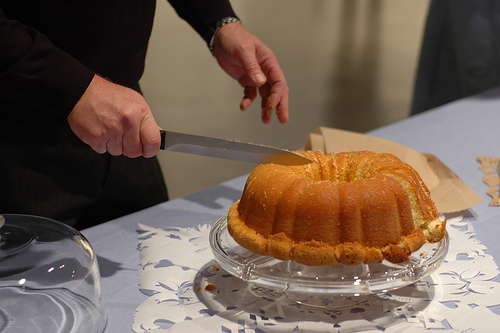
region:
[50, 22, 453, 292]
cutting a cake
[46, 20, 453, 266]
the knife is long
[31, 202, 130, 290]
the glass lid for the cake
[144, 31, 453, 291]
this is a bundt cake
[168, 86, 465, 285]
the cake is on glass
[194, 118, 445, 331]
the cake is golden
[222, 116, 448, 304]
the cake has no frosting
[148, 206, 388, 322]
cake is on white decor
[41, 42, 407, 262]
one hand holds a knife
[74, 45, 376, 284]
about to cut a cake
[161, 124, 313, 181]
silver blade of a knife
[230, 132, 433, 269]
golden colored bundt cake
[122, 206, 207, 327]
lacy white paper table doily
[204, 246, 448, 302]
clear glass cake stand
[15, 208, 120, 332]
clear cake dome topper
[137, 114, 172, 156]
black handle of a knife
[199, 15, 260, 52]
wrist watch on a hand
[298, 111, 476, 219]
brown napkin beside the bundt cake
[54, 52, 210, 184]
hand holding a knife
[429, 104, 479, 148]
grey colored table top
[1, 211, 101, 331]
top of the cake dish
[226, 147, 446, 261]
pound cake on platter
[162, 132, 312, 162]
knife cutting the cake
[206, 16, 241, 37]
bracelet on person's left hand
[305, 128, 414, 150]
brown paper towel on table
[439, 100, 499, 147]
blue table cloth over table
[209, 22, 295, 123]
the person's left hand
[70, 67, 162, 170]
the person's right hand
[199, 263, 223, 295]
cake crumbs on table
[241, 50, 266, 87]
the person's left thumb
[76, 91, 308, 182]
a person holding a knife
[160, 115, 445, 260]
a knife cutting a cake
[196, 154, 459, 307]
a cake on a glass serving dish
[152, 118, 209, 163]
a knife with black handle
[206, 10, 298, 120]
the left hand of a person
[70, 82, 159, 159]
the right hand of a person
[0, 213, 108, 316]
a glass cake pedestal cover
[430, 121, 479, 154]
a light grey table cloth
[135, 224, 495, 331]
a white paper doily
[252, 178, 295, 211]
crumbs on a cake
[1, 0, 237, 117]
sleeves of black shirt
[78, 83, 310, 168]
fingers around knife handle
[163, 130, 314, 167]
blade of sharp knife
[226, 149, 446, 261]
plain cake with slices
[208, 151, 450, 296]
cake on glass dish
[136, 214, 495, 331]
white paper doilie on table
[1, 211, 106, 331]
cover of glass cake safe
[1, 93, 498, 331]
pale blue cloth on table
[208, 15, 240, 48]
silver band on wrist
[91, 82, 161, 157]
hand on end of knife